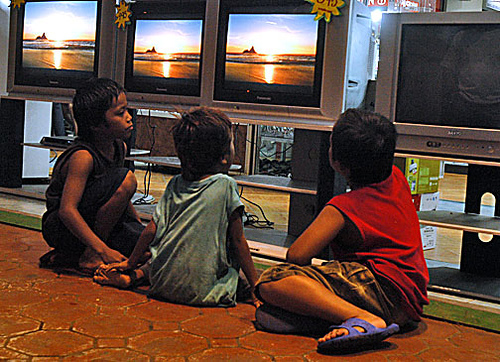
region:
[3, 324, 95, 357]
red brick on ground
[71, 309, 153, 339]
red brick on ground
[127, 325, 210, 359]
red brick on ground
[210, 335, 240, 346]
red brick on ground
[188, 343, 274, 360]
red brick on ground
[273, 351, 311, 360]
red brick on ground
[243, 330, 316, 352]
red brick on ground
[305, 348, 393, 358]
red brick on ground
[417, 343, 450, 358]
red brick on ground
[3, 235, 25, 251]
red brick on ground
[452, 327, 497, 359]
red stone on ground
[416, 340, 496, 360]
red stone on ground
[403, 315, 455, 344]
red stone on ground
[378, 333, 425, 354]
red stone on ground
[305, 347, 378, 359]
red stone on ground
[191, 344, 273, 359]
red stone on ground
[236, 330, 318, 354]
red stone on ground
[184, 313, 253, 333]
red stone on ground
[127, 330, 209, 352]
red stone on ground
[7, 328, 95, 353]
red stone on ground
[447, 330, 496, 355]
red brick on ground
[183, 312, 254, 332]
red brick on ground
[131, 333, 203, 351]
red brick on ground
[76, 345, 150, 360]
red brick on ground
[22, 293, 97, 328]
red brick on ground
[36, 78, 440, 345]
Three boys.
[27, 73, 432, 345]
Three boys sitting on the floor.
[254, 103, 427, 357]
The boy on the right is wearing a red shirt.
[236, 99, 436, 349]
The boy on the right is wearing blue sandals.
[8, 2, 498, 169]
A row of televisions on shelves.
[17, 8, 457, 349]
The boys are looking at the televisions.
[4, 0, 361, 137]
The three televisions on the left are powered on.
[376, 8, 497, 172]
The television on the right is off.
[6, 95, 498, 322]
Open backed shelves are under the televisions.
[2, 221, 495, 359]
The floor is made of red circular tiles.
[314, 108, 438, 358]
boy sitting on floor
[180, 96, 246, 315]
boy sitting on floor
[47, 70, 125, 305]
boy sitting on floor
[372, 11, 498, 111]
tv on the shelf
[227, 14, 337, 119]
tv on the shelf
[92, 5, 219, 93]
tv on the shelf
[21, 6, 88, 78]
tv on the shelf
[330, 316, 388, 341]
the sandal is purple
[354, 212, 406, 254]
the shirt is red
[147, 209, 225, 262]
the shirt is green